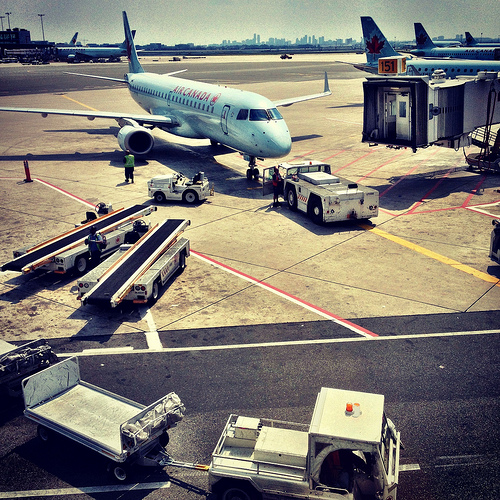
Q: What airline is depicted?
A: Air Canada.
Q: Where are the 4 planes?
A: On the ground.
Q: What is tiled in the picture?
A: Ground.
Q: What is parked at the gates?
A: 3 airplanes.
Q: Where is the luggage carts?
A: On black pavements.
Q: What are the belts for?
A: Moving luggage.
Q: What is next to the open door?
A: A worker.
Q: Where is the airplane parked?
A: On runway.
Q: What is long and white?
A: Airplane.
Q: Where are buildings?
A: In the far distance.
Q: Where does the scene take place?
A: At an airport.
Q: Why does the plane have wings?
A: To be able to fly.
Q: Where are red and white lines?
A: On the tarmac.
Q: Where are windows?
A: On the plane.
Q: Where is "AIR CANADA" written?
A: On side of the plane.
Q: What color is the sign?
A: Orange.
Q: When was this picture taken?
A: During the day.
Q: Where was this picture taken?
A: At an airport.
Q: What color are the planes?
A: White.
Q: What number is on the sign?
A: 151.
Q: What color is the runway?
A: Black.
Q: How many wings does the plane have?
A: Two.